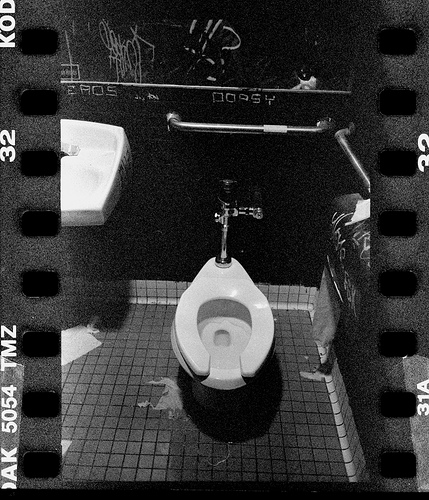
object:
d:
[211, 91, 224, 104]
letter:
[264, 94, 275, 110]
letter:
[250, 92, 262, 105]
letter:
[224, 91, 236, 105]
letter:
[105, 87, 119, 99]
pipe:
[215, 178, 265, 267]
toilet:
[168, 177, 274, 417]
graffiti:
[96, 20, 156, 83]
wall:
[59, 0, 332, 288]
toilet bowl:
[168, 256, 275, 393]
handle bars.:
[163, 111, 336, 135]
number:
[0, 128, 18, 145]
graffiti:
[327, 209, 371, 312]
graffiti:
[118, 143, 133, 191]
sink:
[60, 117, 133, 227]